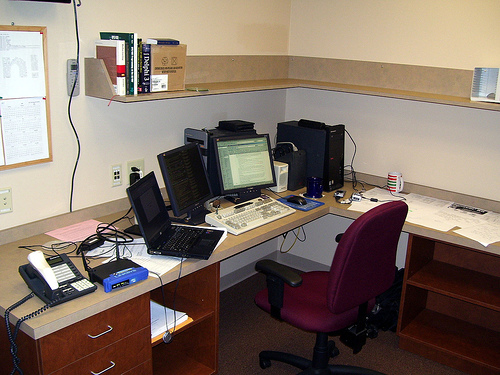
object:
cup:
[386, 171, 404, 194]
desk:
[0, 181, 500, 375]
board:
[0, 25, 54, 171]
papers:
[151, 300, 189, 338]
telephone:
[3, 250, 98, 375]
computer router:
[80, 233, 149, 293]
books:
[94, 30, 180, 96]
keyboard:
[205, 194, 298, 236]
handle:
[87, 325, 113, 339]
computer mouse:
[287, 196, 308, 206]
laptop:
[126, 170, 225, 260]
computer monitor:
[217, 136, 275, 191]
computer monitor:
[163, 145, 212, 211]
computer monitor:
[129, 172, 169, 241]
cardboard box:
[149, 44, 187, 93]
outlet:
[130, 166, 140, 172]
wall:
[1, 0, 289, 230]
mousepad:
[275, 194, 325, 211]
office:
[0, 0, 500, 375]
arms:
[249, 224, 354, 289]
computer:
[156, 142, 215, 226]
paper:
[0, 31, 47, 99]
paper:
[0, 98, 50, 166]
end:
[84, 57, 124, 102]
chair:
[254, 200, 410, 375]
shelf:
[84, 57, 500, 112]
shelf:
[149, 261, 220, 375]